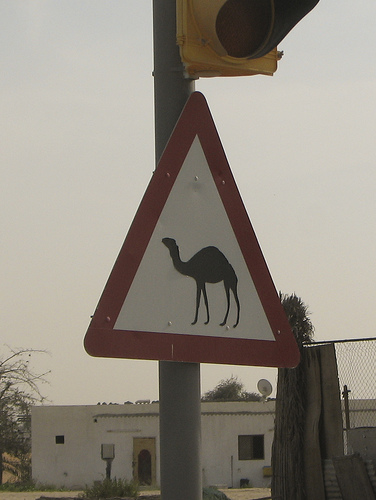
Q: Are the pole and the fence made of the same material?
A: Yes, both the pole and the fence are made of metal.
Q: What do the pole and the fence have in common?
A: The material, both the pole and the fence are metallic.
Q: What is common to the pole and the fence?
A: The material, both the pole and the fence are metallic.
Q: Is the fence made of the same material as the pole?
A: Yes, both the fence and the pole are made of metal.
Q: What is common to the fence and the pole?
A: The material, both the fence and the pole are metallic.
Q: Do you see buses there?
A: No, there are no buses.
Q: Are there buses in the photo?
A: No, there are no buses.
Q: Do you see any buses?
A: No, there are no buses.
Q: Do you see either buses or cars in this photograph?
A: No, there are no buses or cars.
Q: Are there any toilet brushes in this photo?
A: No, there are no toilet brushes.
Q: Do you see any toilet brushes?
A: No, there are no toilet brushes.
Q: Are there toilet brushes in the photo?
A: No, there are no toilet brushes.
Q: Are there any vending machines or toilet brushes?
A: No, there are no toilet brushes or vending machines.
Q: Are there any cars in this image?
A: No, there are no cars.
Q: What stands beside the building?
A: The tree stands beside the building.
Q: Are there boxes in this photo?
A: No, there are no boxes.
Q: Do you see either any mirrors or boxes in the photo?
A: No, there are no boxes or mirrors.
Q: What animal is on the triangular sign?
A: The camel is on the sign.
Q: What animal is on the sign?
A: The camel is on the sign.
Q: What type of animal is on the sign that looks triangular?
A: The animal is a camel.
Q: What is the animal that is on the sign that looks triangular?
A: The animal is a camel.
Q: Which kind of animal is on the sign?
A: The animal is a camel.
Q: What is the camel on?
A: The camel is on the sign.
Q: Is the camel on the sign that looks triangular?
A: Yes, the camel is on the sign.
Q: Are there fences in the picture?
A: Yes, there is a fence.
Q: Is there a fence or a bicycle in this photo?
A: Yes, there is a fence.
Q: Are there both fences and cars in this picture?
A: No, there is a fence but no cars.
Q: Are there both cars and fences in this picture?
A: No, there is a fence but no cars.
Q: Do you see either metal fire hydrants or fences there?
A: Yes, there is a metal fence.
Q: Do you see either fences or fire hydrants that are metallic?
A: Yes, the fence is metallic.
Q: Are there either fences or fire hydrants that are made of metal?
A: Yes, the fence is made of metal.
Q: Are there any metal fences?
A: Yes, there is a metal fence.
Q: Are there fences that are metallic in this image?
A: Yes, there is a metal fence.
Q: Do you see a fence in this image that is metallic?
A: Yes, there is a fence that is metallic.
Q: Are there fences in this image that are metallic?
A: Yes, there is a fence that is metallic.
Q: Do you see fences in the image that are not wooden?
A: Yes, there is a metallic fence.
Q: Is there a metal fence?
A: Yes, there is a fence that is made of metal.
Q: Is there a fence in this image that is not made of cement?
A: Yes, there is a fence that is made of metal.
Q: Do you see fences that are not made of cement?
A: Yes, there is a fence that is made of metal.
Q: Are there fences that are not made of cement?
A: Yes, there is a fence that is made of metal.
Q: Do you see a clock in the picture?
A: No, there are no clocks.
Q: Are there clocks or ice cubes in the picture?
A: No, there are no clocks or ice cubes.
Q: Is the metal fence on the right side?
A: Yes, the fence is on the right of the image.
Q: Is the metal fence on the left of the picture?
A: No, the fence is on the right of the image.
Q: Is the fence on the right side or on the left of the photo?
A: The fence is on the right of the image.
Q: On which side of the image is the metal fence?
A: The fence is on the right of the image.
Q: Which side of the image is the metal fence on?
A: The fence is on the right of the image.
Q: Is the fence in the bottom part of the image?
A: Yes, the fence is in the bottom of the image.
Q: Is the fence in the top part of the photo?
A: No, the fence is in the bottom of the image.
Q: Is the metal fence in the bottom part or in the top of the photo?
A: The fence is in the bottom of the image.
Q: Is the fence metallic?
A: Yes, the fence is metallic.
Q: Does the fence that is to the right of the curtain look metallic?
A: Yes, the fence is metallic.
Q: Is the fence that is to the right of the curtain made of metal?
A: Yes, the fence is made of metal.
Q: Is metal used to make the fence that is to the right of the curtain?
A: Yes, the fence is made of metal.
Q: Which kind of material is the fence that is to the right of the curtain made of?
A: The fence is made of metal.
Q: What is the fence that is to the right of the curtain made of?
A: The fence is made of metal.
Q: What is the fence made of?
A: The fence is made of metal.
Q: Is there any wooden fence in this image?
A: No, there is a fence but it is metallic.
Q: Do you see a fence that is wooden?
A: No, there is a fence but it is metallic.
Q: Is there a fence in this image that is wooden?
A: No, there is a fence but it is metallic.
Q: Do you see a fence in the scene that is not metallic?
A: No, there is a fence but it is metallic.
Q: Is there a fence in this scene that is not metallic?
A: No, there is a fence but it is metallic.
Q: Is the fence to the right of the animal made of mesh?
A: No, the fence is made of metal.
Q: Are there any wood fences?
A: No, there is a fence but it is made of metal.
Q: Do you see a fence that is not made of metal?
A: No, there is a fence but it is made of metal.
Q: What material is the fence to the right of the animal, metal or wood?
A: The fence is made of metal.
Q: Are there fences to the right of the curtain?
A: Yes, there is a fence to the right of the curtain.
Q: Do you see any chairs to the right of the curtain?
A: No, there is a fence to the right of the curtain.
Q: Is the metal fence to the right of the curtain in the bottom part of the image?
A: Yes, the fence is to the right of the curtain.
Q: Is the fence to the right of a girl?
A: No, the fence is to the right of the curtain.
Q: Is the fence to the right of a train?
A: No, the fence is to the right of the animal.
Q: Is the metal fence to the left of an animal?
A: No, the fence is to the right of an animal.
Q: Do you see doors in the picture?
A: Yes, there is a door.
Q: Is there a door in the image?
A: Yes, there is a door.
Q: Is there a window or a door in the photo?
A: Yes, there is a door.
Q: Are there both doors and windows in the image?
A: Yes, there are both a door and a window.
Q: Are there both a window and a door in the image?
A: Yes, there are both a door and a window.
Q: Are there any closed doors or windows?
A: Yes, there is a closed door.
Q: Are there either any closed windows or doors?
A: Yes, there is a closed door.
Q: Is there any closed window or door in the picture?
A: Yes, there is a closed door.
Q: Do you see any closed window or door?
A: Yes, there is a closed door.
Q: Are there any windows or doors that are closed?
A: Yes, the door is closed.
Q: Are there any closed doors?
A: Yes, there is a closed door.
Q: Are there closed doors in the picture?
A: Yes, there is a closed door.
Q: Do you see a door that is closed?
A: Yes, there is a door that is closed.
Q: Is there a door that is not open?
A: Yes, there is an closed door.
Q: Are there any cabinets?
A: No, there are no cabinets.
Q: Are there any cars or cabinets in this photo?
A: No, there are no cabinets or cars.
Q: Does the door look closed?
A: Yes, the door is closed.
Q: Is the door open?
A: No, the door is closed.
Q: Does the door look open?
A: No, the door is closed.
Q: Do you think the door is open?
A: No, the door is closed.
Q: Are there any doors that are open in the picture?
A: No, there is a door but it is closed.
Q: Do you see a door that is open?
A: No, there is a door but it is closed.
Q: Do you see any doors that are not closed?
A: No, there is a door but it is closed.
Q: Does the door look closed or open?
A: The door is closed.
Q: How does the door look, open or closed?
A: The door is closed.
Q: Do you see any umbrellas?
A: No, there are no umbrellas.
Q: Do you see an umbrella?
A: No, there are no umbrellas.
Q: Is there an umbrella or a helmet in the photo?
A: No, there are no umbrellas or helmets.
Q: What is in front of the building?
A: The shrubs are in front of the building.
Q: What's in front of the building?
A: The shrubs are in front of the building.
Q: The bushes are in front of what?
A: The bushes are in front of the building.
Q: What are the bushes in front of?
A: The bushes are in front of the building.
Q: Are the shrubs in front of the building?
A: Yes, the shrubs are in front of the building.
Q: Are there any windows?
A: Yes, there is a window.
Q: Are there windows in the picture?
A: Yes, there is a window.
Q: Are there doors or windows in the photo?
A: Yes, there is a window.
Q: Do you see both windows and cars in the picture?
A: No, there is a window but no cars.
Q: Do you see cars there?
A: No, there are no cars.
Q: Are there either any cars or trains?
A: No, there are no cars or trains.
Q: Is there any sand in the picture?
A: Yes, there is sand.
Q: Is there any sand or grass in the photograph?
A: Yes, there is sand.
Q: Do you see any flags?
A: No, there are no flags.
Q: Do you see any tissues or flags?
A: No, there are no flags or tissues.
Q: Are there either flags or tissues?
A: No, there are no flags or tissues.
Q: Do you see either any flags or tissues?
A: No, there are no flags or tissues.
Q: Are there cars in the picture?
A: No, there are no cars.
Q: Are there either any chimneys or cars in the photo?
A: No, there are no cars or chimneys.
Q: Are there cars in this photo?
A: No, there are no cars.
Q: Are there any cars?
A: No, there are no cars.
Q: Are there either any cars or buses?
A: No, there are no cars or buses.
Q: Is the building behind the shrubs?
A: Yes, the building is behind the shrubs.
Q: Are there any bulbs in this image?
A: No, there are no bulbs.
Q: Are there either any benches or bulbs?
A: No, there are no bulbs or benches.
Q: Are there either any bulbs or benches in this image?
A: No, there are no bulbs or benches.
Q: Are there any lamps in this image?
A: No, there are no lamps.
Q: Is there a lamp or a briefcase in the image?
A: No, there are no lamps or briefcases.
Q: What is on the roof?
A: The satellite dish is on the roof.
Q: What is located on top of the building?
A: The satellite is on top of the building.